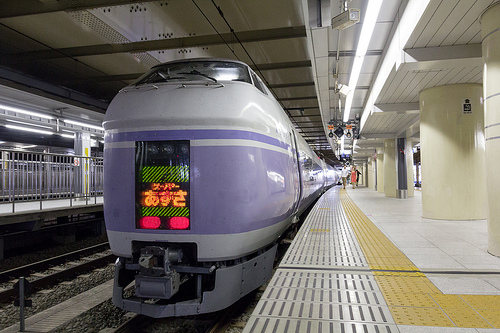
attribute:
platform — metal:
[243, 185, 400, 332]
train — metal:
[87, 49, 348, 329]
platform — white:
[312, 180, 436, 323]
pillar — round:
[417, 87, 479, 227]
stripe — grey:
[168, 98, 307, 169]